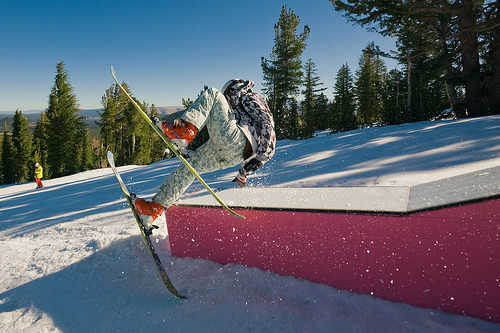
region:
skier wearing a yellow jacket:
[31, 160, 46, 190]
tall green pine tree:
[42, 57, 85, 183]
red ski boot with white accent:
[153, 109, 196, 158]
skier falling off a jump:
[102, 70, 284, 235]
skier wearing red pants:
[31, 163, 44, 189]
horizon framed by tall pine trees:
[11, 52, 179, 136]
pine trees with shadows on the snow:
[341, 0, 493, 167]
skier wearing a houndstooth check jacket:
[216, 68, 280, 185]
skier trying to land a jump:
[116, 75, 276, 287]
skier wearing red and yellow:
[30, 160, 44, 192]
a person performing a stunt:
[51, 42, 298, 304]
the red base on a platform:
[253, 211, 467, 290]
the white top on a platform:
[185, 167, 497, 210]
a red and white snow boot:
[129, 188, 166, 228]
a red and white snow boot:
[154, 110, 199, 147]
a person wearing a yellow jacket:
[17, 157, 59, 200]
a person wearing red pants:
[23, 160, 58, 191]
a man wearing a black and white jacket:
[70, 60, 282, 308]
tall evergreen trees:
[7, 76, 164, 168]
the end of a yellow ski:
[105, 60, 148, 123]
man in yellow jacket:
[26, 157, 53, 194]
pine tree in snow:
[354, 43, 403, 122]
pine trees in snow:
[273, 10, 483, 127]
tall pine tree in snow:
[49, 67, 99, 186]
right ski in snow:
[105, 140, 197, 309]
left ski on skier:
[115, 60, 245, 235]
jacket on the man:
[225, 70, 274, 178]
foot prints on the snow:
[15, 212, 113, 297]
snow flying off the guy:
[290, 230, 392, 287]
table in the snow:
[432, 100, 457, 125]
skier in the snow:
[95, 49, 272, 298]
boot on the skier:
[160, 95, 200, 153]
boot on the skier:
[135, 190, 166, 230]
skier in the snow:
[23, 151, 48, 186]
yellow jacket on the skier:
[28, 165, 48, 177]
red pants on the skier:
[30, 175, 45, 190]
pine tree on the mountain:
[46, 63, 91, 170]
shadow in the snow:
[23, 250, 129, 315]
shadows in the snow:
[326, 130, 446, 171]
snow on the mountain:
[17, 213, 99, 268]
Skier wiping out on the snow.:
[84, 74, 287, 305]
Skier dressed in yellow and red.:
[26, 151, 52, 195]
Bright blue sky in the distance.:
[13, 25, 209, 62]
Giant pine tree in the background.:
[20, 44, 97, 173]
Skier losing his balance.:
[35, 57, 309, 308]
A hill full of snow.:
[318, 125, 468, 163]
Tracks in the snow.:
[10, 225, 120, 318]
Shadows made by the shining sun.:
[13, 174, 110, 247]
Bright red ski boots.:
[152, 114, 204, 150]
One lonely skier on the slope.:
[25, 149, 59, 197]